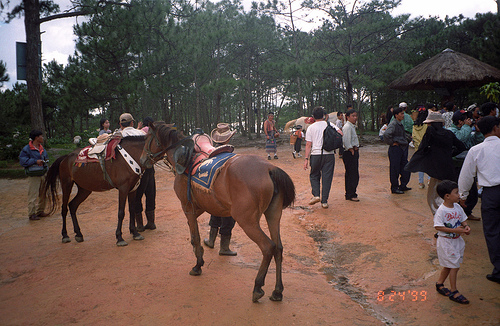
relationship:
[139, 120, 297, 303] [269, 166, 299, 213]
brown horse has tail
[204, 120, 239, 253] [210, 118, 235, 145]
guy wearing hat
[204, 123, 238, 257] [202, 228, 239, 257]
guy wearing boots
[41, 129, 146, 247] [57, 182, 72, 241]
brown horse has leg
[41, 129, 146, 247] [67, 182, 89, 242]
brown horse has leg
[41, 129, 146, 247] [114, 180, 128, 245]
brown horse has leg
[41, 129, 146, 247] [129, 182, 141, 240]
brown horse has leg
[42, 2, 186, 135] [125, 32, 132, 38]
pine tree has needle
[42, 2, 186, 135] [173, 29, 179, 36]
pine tree has needle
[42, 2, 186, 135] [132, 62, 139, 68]
pine tree has needle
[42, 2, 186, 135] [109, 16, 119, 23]
pine tree has needle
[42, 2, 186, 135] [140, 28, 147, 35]
pine tree has needle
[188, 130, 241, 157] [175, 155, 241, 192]
saddle on blanket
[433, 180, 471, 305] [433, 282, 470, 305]
boy wearing sandals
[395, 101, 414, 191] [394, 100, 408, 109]
man wearing cap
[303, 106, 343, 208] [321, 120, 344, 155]
man carrying backpack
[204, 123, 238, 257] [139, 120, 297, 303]
guy standing by brown horse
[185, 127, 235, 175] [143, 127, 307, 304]
saddle on horse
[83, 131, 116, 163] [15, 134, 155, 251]
saddle on horse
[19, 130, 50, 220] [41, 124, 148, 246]
man standing near horse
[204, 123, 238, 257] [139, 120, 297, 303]
guy standing near brown horse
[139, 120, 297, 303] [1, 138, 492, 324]
brown horse standing on dirt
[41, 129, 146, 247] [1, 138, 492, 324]
brown horse standing on dirt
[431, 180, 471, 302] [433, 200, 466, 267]
boy wearing clothes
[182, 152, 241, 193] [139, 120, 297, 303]
blanket on brown horse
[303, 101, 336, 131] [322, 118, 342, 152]
man wearing backpack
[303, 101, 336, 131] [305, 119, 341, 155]
man wearing shirt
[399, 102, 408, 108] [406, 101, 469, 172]
cap on person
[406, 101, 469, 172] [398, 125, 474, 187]
person wearing a cape